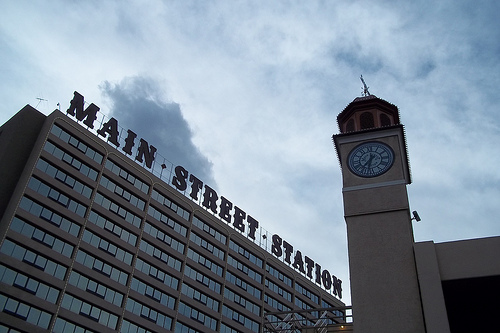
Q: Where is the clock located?
A: On the clock tower.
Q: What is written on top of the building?
A: Main Street Station.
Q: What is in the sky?
A: Clouds.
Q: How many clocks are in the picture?
A: 1.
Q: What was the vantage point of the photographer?
A: The photographer was positioned below the focal points of interest, here.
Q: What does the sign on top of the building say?
A: Main Street Station.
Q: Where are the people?
A: There are none.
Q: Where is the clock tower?
A: To the right of the station.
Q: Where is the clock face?
A: On the tower.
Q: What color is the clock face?
A: White.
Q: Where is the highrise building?
A: .to the left of the clocktower.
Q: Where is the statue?
A: Atop the clocktower.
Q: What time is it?
A: Seven thirty-one.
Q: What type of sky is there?
A: Overcast.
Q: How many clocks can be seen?
A: One.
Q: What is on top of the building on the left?
A: Sign.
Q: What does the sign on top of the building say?
A: Main Street Station.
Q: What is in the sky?
A: Clouds.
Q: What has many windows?
A: Building on the left.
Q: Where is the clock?
A: Clock tower.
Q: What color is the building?
A: Tan.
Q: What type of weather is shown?
A: Cloudy.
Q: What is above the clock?
A: Windows.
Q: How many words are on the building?
A: Three.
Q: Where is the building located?
A: Downtown.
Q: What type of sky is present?
A: Overcast.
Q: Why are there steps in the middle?
A: To reach the clock tower.